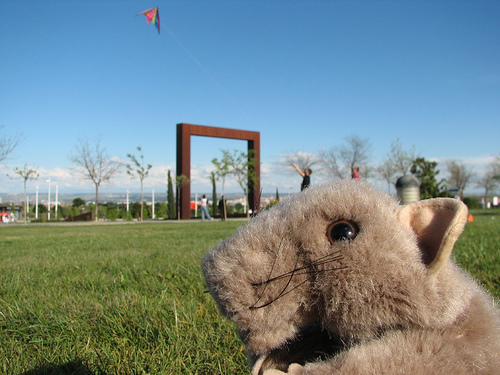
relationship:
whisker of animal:
[252, 251, 342, 286] [200, 179, 499, 374]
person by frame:
[195, 190, 216, 220] [175, 122, 260, 219]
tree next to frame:
[166, 167, 176, 221] [175, 120, 262, 217]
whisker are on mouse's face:
[251, 256, 300, 309] [197, 182, 484, 355]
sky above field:
[0, 2, 498, 193] [0, 213, 499, 375]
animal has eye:
[195, 181, 489, 373] [326, 217, 361, 243]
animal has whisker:
[195, 181, 489, 373] [247, 247, 339, 281]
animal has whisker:
[195, 181, 489, 373] [253, 263, 353, 283]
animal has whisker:
[195, 181, 489, 373] [251, 276, 316, 311]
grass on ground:
[58, 229, 237, 334] [4, 212, 371, 372]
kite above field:
[136, 6, 161, 34] [0, 213, 499, 375]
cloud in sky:
[29, 161, 172, 186] [0, 2, 498, 193]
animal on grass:
[195, 181, 489, 373] [5, 215, 493, 371]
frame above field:
[175, 122, 260, 219] [0, 204, 482, 373]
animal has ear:
[200, 179, 499, 374] [365, 191, 499, 253]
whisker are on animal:
[252, 251, 342, 286] [195, 181, 489, 373]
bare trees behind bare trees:
[74, 143, 123, 221] [63, 136, 158, 230]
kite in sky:
[134, 3, 168, 38] [0, 2, 498, 193]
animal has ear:
[200, 179, 499, 374] [403, 197, 467, 275]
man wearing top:
[288, 155, 314, 192] [297, 169, 312, 190]